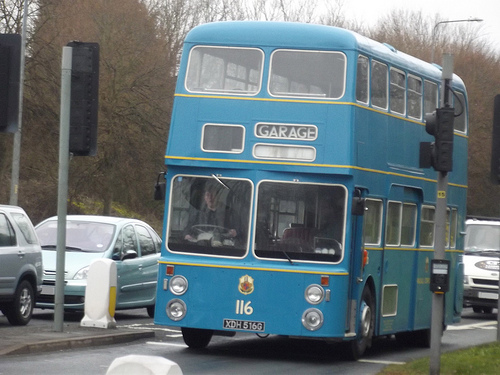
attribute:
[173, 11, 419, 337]
bus — blue, vblue, double decker, double deckery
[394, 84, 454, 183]
signal — black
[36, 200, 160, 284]
car — whtie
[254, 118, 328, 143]
license — whtie